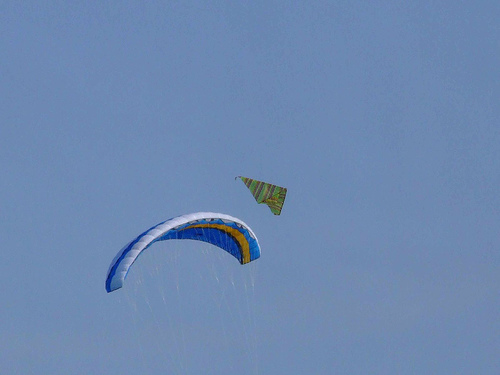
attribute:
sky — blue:
[73, 21, 468, 94]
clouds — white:
[417, 112, 477, 281]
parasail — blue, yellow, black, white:
[65, 158, 347, 345]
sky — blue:
[2, 2, 498, 372]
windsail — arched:
[99, 205, 269, 373]